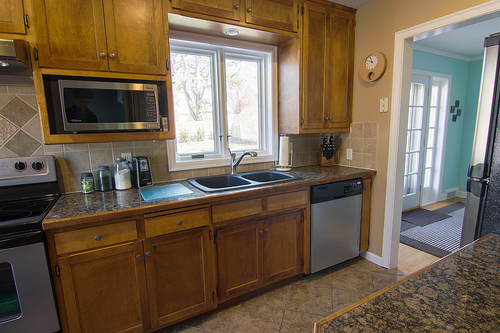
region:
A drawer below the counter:
[147, 208, 208, 238]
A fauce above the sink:
[226, 148, 256, 174]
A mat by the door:
[402, 204, 452, 226]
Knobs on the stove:
[13, 158, 41, 170]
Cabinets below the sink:
[217, 207, 307, 303]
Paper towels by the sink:
[276, 135, 291, 165]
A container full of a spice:
[116, 155, 129, 190]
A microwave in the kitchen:
[58, 80, 160, 128]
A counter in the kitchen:
[51, 157, 373, 219]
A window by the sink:
[172, 56, 267, 166]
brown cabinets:
[217, 223, 314, 282]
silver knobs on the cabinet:
[256, 226, 271, 238]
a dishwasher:
[310, 189, 360, 264]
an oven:
[5, 255, 51, 322]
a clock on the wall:
[355, 55, 384, 82]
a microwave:
[47, 83, 158, 127]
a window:
[171, 54, 261, 153]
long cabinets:
[304, 12, 351, 131]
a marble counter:
[387, 278, 489, 328]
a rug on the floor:
[408, 209, 437, 223]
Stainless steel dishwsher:
[290, 158, 374, 278]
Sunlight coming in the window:
[155, 28, 287, 167]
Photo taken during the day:
[35, 1, 492, 263]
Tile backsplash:
[0, 95, 387, 181]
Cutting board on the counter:
[130, 180, 207, 204]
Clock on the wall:
[347, 43, 397, 94]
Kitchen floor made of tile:
[143, 256, 378, 331]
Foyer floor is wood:
[397, 194, 472, 276]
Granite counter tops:
[331, 258, 498, 327]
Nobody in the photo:
[0, 22, 495, 328]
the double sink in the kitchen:
[185, 168, 302, 195]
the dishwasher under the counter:
[309, 178, 361, 273]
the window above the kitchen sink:
[164, 36, 281, 172]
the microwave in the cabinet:
[56, 77, 161, 133]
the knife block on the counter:
[321, 133, 335, 165]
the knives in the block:
[321, 131, 336, 159]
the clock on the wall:
[357, 51, 385, 83]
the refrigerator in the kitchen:
[456, 28, 499, 250]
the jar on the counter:
[113, 156, 133, 191]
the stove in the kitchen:
[1, 154, 61, 331]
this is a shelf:
[301, 25, 346, 123]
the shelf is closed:
[303, 21, 350, 118]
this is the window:
[175, 49, 272, 149]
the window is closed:
[175, 46, 265, 147]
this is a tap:
[224, 150, 258, 175]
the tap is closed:
[225, 144, 263, 174]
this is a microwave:
[46, 76, 165, 139]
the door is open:
[398, 15, 482, 255]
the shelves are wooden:
[134, 230, 234, 317]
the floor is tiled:
[327, 266, 372, 303]